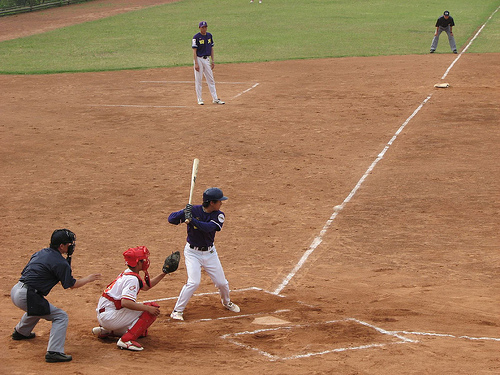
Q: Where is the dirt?
A: On the baseball field.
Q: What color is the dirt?
A: Brown.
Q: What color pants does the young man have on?
A: White.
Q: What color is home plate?
A: White.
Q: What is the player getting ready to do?
A: Swing the bat.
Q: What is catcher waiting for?
A: To catch the ball.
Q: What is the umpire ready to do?
A: Make the call.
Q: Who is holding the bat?
A: The player.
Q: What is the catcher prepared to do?
A: Catch the ball.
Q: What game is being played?
A: Baseball.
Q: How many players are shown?
A: 5.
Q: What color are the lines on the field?
A: White.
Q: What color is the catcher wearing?
A: Red and white.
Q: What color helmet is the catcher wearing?
A: Red.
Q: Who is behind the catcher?
A: Umpire.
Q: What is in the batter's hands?
A: Bat.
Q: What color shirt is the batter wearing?
A: Blue.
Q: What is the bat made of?
A: Wood.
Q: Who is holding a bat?
A: The batter.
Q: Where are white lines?
A: On the ground.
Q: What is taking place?
A: A baseball game.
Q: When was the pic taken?
A: During the day.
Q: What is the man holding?
A: A bat.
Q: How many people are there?
A: 5.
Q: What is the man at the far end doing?
A: Bending.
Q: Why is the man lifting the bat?
A: Ready to hit the ball.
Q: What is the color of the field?
A: Brown.